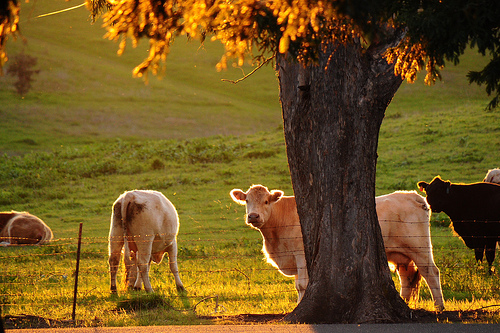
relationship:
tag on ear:
[418, 183, 425, 188] [416, 181, 427, 191]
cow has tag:
[417, 174, 500, 276] [418, 183, 425, 188]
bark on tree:
[311, 114, 354, 234] [83, 0, 443, 323]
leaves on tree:
[83, 0, 444, 85] [82, 0, 497, 330]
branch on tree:
[216, 56, 279, 91] [286, 34, 398, 309]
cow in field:
[106, 186, 184, 293] [0, 2, 495, 324]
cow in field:
[402, 169, 497, 273] [387, 120, 493, 176]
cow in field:
[2, 205, 69, 249] [18, 97, 178, 186]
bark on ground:
[279, 60, 411, 324] [1, 315, 496, 332]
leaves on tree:
[83, 0, 444, 85] [83, 0, 443, 323]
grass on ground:
[0, 1, 498, 331] [100, 150, 187, 177]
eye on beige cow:
[265, 201, 268, 205] [228, 183, 445, 313]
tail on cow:
[118, 191, 131, 279] [106, 186, 184, 293]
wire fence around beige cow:
[5, 225, 498, 331] [228, 183, 445, 313]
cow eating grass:
[106, 188, 188, 293] [0, 1, 498, 331]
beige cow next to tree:
[228, 183, 445, 313] [82, 0, 497, 330]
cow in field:
[480, 166, 498, 181] [0, 2, 495, 324]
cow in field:
[417, 174, 500, 276] [0, 2, 495, 324]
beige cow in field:
[228, 183, 445, 313] [0, 2, 495, 324]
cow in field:
[106, 188, 188, 293] [0, 2, 495, 324]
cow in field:
[0, 210, 53, 246] [0, 2, 495, 324]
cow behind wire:
[0, 210, 53, 246] [6, 216, 493, 331]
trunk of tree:
[266, 31, 407, 325] [82, 0, 497, 330]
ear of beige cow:
[269, 188, 283, 203] [228, 183, 445, 313]